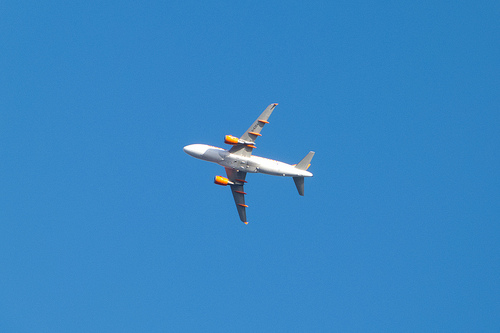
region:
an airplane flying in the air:
[170, 100, 315, 225]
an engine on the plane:
[205, 170, 230, 187]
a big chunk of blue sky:
[325, 5, 495, 315]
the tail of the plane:
[290, 145, 312, 195]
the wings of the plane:
[220, 96, 277, 221]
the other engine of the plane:
[223, 135, 256, 150]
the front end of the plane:
[176, 137, 208, 158]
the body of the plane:
[188, 137, 318, 179]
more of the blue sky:
[6, 223, 466, 324]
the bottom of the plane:
[210, 150, 256, 175]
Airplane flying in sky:
[163, 85, 356, 241]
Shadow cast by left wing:
[195, 138, 279, 215]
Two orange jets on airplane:
[216, 128, 246, 194]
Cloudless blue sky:
[26, 19, 143, 132]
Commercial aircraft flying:
[158, 94, 335, 244]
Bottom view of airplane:
[146, 84, 340, 252]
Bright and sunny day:
[20, 19, 185, 132]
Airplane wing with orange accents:
[217, 92, 289, 162]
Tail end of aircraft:
[291, 146, 323, 207]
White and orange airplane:
[143, 79, 343, 251]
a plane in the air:
[82, 70, 482, 301]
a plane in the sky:
[164, 67, 347, 256]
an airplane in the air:
[165, 70, 474, 309]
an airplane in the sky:
[154, 67, 341, 245]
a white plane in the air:
[169, 77, 343, 226]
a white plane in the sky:
[148, 82, 335, 230]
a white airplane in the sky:
[179, 81, 341, 225]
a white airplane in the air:
[175, 75, 342, 232]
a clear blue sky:
[21, 125, 158, 280]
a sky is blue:
[59, 154, 198, 321]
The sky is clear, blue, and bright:
[26, 25, 177, 290]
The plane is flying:
[122, 86, 368, 238]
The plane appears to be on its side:
[125, 72, 358, 223]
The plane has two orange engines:
[196, 123, 256, 190]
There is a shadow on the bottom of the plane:
[195, 137, 275, 175]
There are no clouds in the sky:
[22, 51, 162, 252]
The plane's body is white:
[170, 115, 337, 201]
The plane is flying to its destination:
[161, 85, 341, 245]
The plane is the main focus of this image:
[141, 85, 378, 227]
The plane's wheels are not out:
[195, 140, 305, 196]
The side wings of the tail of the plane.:
[291, 152, 322, 198]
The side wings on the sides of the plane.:
[217, 116, 274, 237]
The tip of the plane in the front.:
[180, 140, 199, 157]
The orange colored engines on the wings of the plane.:
[211, 119, 249, 186]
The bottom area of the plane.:
[212, 147, 306, 180]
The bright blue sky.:
[12, 5, 499, 320]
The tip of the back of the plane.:
[307, 168, 317, 180]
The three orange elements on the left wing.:
[240, 115, 267, 152]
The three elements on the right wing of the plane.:
[236, 173, 255, 228]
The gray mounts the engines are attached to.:
[225, 135, 261, 194]